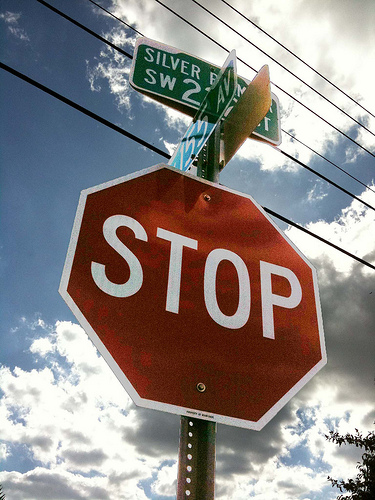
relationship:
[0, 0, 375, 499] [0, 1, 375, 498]
cloud in sky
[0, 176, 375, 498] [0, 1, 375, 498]
cloud in sky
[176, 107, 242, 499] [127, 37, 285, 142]
pole has sign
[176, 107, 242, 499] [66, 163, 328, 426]
pole has sign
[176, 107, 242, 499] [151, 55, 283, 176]
pole has sign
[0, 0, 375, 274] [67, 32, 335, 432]
lines above signs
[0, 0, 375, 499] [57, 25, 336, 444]
cloud beside sign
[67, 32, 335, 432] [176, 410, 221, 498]
signs on pole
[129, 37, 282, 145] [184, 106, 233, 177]
green signs on pole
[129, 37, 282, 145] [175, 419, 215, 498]
green signs on pole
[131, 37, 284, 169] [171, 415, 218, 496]
green signs on pole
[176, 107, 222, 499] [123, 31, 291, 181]
pole with signs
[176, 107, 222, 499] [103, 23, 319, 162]
pole with street signs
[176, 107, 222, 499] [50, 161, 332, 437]
pole holding sign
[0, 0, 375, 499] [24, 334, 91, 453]
cloud backlit by sunlight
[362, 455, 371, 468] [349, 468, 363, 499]
leaves on tree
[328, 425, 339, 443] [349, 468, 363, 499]
leaf on tree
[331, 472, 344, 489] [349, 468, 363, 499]
leaf on tree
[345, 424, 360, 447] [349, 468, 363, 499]
leaf on tree